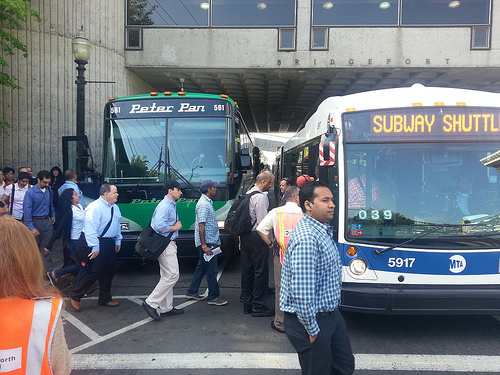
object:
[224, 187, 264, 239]
backpack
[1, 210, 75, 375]
safety guard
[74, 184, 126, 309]
people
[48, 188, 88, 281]
people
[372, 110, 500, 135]
digital display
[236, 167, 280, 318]
people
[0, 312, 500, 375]
ground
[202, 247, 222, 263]
paper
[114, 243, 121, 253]
hand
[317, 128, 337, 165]
mirror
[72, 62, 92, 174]
lampost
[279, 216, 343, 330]
shirt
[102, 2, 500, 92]
buildings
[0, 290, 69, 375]
vest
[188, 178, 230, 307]
man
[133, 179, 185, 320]
man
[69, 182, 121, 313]
man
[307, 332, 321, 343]
hand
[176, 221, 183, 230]
hand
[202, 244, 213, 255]
hand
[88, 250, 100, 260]
hand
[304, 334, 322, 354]
pocket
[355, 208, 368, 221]
number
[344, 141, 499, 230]
window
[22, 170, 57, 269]
people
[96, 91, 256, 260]
bus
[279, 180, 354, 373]
man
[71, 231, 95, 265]
black bag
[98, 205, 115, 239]
strap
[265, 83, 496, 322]
bus